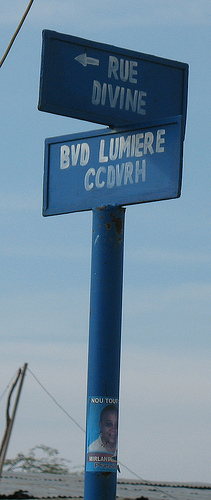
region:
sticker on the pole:
[86, 394, 123, 474]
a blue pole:
[88, 347, 116, 395]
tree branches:
[26, 442, 64, 471]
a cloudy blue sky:
[159, 389, 203, 426]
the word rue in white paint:
[107, 55, 137, 82]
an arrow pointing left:
[73, 50, 98, 66]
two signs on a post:
[29, 29, 188, 218]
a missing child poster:
[85, 394, 118, 472]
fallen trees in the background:
[3, 445, 84, 476]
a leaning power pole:
[0, 363, 28, 471]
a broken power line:
[26, 366, 180, 498]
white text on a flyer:
[89, 457, 110, 461]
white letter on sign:
[107, 54, 118, 80]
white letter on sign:
[119, 57, 128, 83]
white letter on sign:
[128, 59, 138, 84]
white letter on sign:
[90, 78, 101, 106]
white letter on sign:
[100, 82, 106, 107]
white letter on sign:
[107, 82, 119, 108]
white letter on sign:
[119, 87, 124, 110]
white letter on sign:
[124, 88, 137, 113]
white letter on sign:
[137, 89, 147, 114]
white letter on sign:
[155, 128, 165, 153]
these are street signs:
[36, 80, 187, 429]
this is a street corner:
[26, 31, 180, 257]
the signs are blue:
[32, 34, 150, 245]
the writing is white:
[20, 49, 170, 209]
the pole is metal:
[69, 216, 184, 390]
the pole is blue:
[60, 224, 175, 388]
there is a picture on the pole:
[60, 391, 161, 498]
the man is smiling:
[82, 396, 172, 484]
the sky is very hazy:
[150, 303, 200, 382]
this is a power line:
[12, 355, 74, 455]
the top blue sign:
[37, 29, 188, 137]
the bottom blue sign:
[42, 114, 183, 215]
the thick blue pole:
[84, 205, 126, 498]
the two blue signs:
[37, 28, 188, 215]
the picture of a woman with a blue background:
[87, 395, 118, 471]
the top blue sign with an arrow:
[38, 28, 188, 137]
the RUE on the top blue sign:
[37, 28, 188, 139]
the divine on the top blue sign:
[37, 29, 188, 146]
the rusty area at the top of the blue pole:
[82, 206, 123, 498]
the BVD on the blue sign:
[40, 114, 185, 217]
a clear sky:
[153, 23, 183, 43]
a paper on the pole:
[87, 396, 119, 470]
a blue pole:
[90, 341, 116, 393]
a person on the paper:
[96, 409, 118, 451]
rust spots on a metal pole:
[96, 205, 124, 245]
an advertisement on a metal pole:
[85, 395, 120, 473]